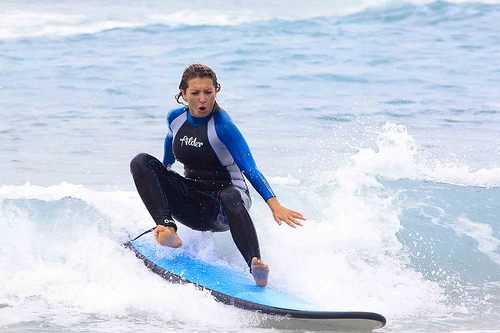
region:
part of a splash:
[358, 150, 416, 222]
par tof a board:
[233, 288, 262, 303]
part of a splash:
[337, 119, 371, 186]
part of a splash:
[320, 180, 360, 253]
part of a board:
[205, 233, 245, 309]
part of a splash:
[323, 218, 342, 250]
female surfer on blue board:
[101, 71, 358, 319]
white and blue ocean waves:
[18, 16, 69, 60]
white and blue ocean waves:
[14, 185, 54, 229]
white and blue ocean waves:
[324, 5, 442, 87]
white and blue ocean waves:
[352, 126, 423, 173]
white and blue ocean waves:
[30, 219, 78, 273]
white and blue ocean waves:
[358, 43, 458, 105]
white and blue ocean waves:
[271, 55, 325, 117]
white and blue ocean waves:
[402, 159, 464, 230]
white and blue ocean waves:
[35, 79, 57, 126]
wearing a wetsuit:
[130, 98, 250, 208]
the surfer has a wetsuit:
[117, 82, 262, 238]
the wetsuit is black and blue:
[141, 109, 238, 207]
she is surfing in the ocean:
[106, 250, 358, 327]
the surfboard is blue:
[135, 238, 395, 331]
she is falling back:
[110, 91, 300, 296]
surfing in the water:
[63, 75, 420, 310]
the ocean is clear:
[5, 16, 427, 177]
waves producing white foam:
[47, 178, 407, 307]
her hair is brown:
[163, 66, 218, 89]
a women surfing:
[124, 52, 381, 332]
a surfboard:
[214, 275, 272, 299]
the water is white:
[20, 212, 107, 298]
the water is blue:
[332, 27, 450, 129]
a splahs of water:
[354, 131, 404, 175]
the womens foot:
[246, 256, 277, 290]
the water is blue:
[32, 68, 113, 138]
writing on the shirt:
[173, 133, 206, 153]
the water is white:
[378, 122, 418, 180]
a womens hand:
[266, 200, 304, 232]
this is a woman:
[125, 72, 262, 190]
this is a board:
[110, 267, 289, 295]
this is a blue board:
[210, 221, 315, 311]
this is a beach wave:
[320, 156, 352, 206]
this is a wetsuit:
[223, 152, 243, 202]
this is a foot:
[128, 186, 205, 288]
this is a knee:
[115, 121, 149, 153]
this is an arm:
[218, 135, 320, 252]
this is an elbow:
[247, 164, 260, 187]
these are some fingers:
[285, 216, 298, 261]